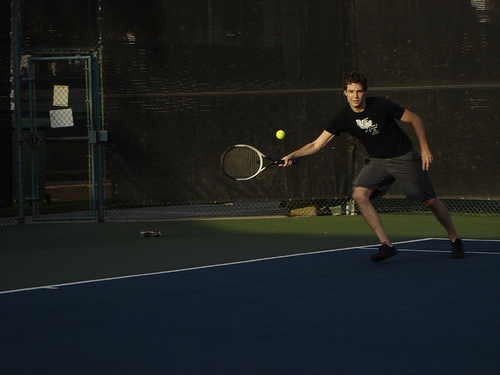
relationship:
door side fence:
[6, 44, 109, 208] [105, 82, 498, 212]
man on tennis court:
[275, 69, 465, 261] [7, 238, 497, 373]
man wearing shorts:
[275, 69, 465, 261] [347, 156, 432, 198]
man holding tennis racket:
[275, 69, 465, 261] [220, 141, 300, 184]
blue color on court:
[217, 277, 368, 363] [12, 208, 443, 366]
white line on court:
[1, 238, 436, 292] [1, 238, 498, 372]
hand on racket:
[278, 156, 295, 166] [217, 142, 297, 181]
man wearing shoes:
[275, 69, 468, 265] [370, 241, 398, 263]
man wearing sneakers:
[275, 69, 468, 265] [447, 236, 465, 260]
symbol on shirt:
[354, 115, 378, 134] [320, 102, 425, 184]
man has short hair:
[275, 69, 468, 265] [340, 68, 371, 93]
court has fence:
[0, 209, 496, 367] [3, 0, 496, 209]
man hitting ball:
[275, 69, 465, 261] [267, 121, 293, 150]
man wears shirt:
[275, 69, 465, 261] [323, 97, 413, 159]